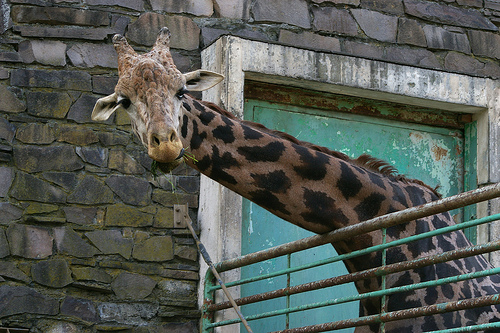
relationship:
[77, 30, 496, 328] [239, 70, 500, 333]
giraffe behind door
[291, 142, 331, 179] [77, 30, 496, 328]
stripe on giraffe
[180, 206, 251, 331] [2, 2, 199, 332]
pole on wall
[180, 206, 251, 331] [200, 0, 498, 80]
pole on wall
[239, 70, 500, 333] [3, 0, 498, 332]
door attached to wall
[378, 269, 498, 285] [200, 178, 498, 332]
paint on railing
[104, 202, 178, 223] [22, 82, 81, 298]
green tiles on wall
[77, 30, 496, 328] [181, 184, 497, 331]
giraffe looking over railing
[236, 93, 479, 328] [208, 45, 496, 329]
paint on door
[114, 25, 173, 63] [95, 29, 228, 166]
horns on head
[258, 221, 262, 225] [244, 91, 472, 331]
paint on door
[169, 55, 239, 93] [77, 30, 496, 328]
ear of giraffe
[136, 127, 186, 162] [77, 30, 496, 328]
nose of giraffe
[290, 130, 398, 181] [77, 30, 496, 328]
hair on back of giraffe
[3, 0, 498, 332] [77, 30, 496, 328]
wall next to giraffe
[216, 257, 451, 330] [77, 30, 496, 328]
bars next to giraffe